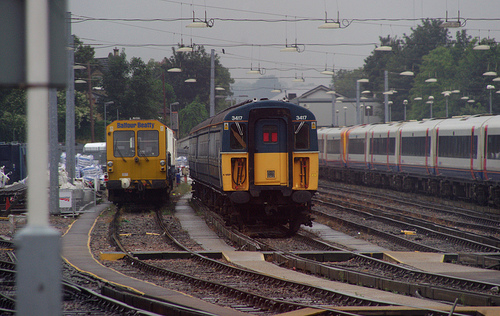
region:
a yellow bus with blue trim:
[105, 117, 176, 203]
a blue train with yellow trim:
[188, 99, 319, 223]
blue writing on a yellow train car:
[113, 121, 155, 129]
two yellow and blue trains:
[105, 98, 320, 238]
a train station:
[2, 2, 499, 312]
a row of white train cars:
[320, 114, 498, 203]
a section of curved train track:
[112, 209, 447, 314]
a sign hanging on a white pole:
[0, 1, 69, 313]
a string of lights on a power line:
[65, 10, 497, 29]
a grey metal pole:
[208, 47, 216, 114]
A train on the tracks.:
[184, 85, 338, 255]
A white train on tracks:
[331, 109, 498, 203]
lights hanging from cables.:
[178, 15, 498, 107]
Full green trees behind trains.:
[74, 36, 235, 126]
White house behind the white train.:
[292, 80, 393, 125]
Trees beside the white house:
[341, 18, 494, 120]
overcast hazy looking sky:
[89, 10, 435, 60]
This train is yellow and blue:
[185, 92, 333, 229]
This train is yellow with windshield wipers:
[100, 110, 182, 213]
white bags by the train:
[75, 143, 106, 194]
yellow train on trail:
[76, 66, 396, 313]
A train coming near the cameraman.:
[187, 95, 319, 232]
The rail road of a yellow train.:
[192, 205, 498, 315]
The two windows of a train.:
[110, 125, 160, 159]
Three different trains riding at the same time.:
[102, 95, 497, 225]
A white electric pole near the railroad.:
[12, 0, 64, 312]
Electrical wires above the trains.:
[70, 12, 498, 29]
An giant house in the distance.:
[285, 82, 385, 125]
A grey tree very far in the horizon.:
[230, 72, 285, 99]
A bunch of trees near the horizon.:
[0, 35, 233, 138]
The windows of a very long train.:
[315, 134, 497, 161]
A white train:
[323, 100, 488, 223]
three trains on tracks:
[98, 87, 462, 256]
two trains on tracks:
[98, 102, 344, 242]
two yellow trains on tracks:
[99, 81, 345, 256]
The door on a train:
[238, 96, 301, 215]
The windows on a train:
[345, 121, 496, 169]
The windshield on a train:
[100, 121, 171, 170]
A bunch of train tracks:
[94, 215, 480, 297]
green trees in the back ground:
[105, 49, 225, 110]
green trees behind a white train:
[355, 40, 498, 198]